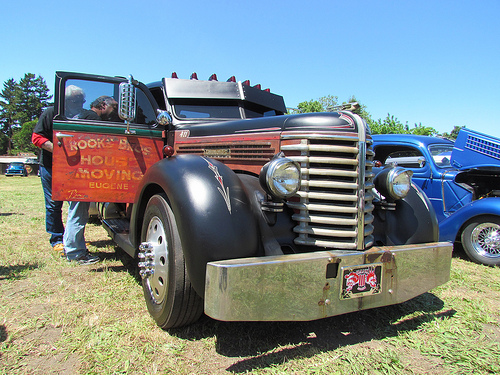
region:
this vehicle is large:
[31, 62, 460, 334]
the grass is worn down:
[2, 177, 496, 373]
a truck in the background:
[4, 158, 30, 180]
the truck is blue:
[3, 159, 25, 181]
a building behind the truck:
[1, 149, 43, 176]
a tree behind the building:
[0, 72, 51, 152]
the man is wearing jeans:
[32, 163, 70, 245]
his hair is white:
[58, 81, 87, 101]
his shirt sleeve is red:
[22, 128, 54, 147]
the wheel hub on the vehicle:
[132, 214, 174, 305]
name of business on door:
[70, 134, 150, 196]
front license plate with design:
[342, 265, 380, 295]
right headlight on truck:
[259, 156, 307, 198]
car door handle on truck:
[55, 128, 72, 146]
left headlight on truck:
[378, 164, 423, 200]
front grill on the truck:
[311, 138, 381, 245]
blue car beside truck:
[421, 133, 495, 246]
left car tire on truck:
[143, 198, 196, 337]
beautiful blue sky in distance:
[283, 15, 418, 58]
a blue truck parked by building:
[6, 155, 27, 182]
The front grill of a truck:
[275, 105, 388, 259]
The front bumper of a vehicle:
[200, 238, 456, 320]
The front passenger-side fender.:
[125, 150, 262, 310]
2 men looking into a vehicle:
[33, 80, 132, 270]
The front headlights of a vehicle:
[255, 153, 411, 217]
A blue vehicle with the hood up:
[360, 125, 499, 270]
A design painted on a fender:
[190, 148, 237, 216]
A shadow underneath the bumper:
[194, 292, 461, 367]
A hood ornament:
[320, 96, 367, 124]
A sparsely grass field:
[2, 175, 499, 373]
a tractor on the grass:
[32, 57, 456, 364]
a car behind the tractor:
[357, 127, 498, 268]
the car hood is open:
[449, 125, 499, 207]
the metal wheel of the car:
[470, 224, 497, 259]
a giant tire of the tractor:
[126, 154, 259, 334]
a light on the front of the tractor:
[257, 144, 300, 199]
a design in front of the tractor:
[337, 262, 387, 299]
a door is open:
[50, 66, 163, 204]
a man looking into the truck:
[57, 94, 135, 268]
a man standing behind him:
[30, 79, 88, 245]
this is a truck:
[41, 75, 437, 308]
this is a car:
[373, 103, 499, 243]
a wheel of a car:
[106, 196, 219, 345]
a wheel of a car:
[462, 202, 499, 259]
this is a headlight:
[248, 151, 320, 213]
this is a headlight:
[380, 161, 422, 200]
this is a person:
[60, 90, 117, 270]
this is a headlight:
[20, 84, 88, 261]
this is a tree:
[0, 78, 25, 163]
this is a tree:
[16, 68, 54, 136]